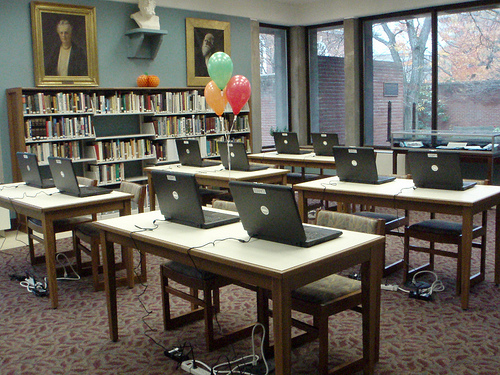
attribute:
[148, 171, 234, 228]
laptop — open, black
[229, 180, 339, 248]
laptop — open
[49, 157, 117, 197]
laptop — open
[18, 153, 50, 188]
laptop — open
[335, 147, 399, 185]
laptop — open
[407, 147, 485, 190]
laptop — open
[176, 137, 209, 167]
laptop — open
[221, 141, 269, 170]
laptop — open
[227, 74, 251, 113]
balloon — filled, red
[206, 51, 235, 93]
balloon — filled, green, floating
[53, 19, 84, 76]
man — elderly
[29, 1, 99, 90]
portrait — framed, large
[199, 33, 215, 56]
woman — elderly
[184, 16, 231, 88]
portrait — framed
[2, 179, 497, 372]
floor — carpet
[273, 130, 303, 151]
laptop — open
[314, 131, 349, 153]
laptop — open, black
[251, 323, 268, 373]
cord — white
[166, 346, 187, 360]
port — black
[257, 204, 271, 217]
logo — white, circular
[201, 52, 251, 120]
balloons — colorful, clustered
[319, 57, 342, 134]
bricks — red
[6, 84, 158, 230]
shelf — large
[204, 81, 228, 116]
balloon — orange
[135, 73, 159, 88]
decoration — orange